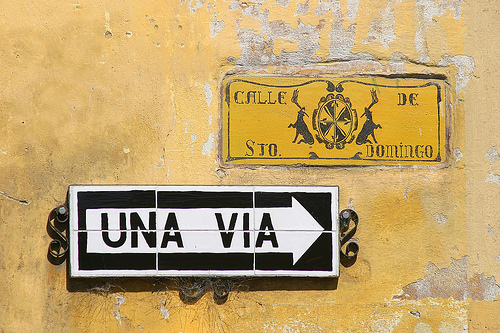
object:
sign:
[65, 184, 339, 279]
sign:
[223, 69, 451, 166]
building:
[0, 1, 500, 332]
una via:
[98, 210, 280, 249]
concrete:
[399, 255, 496, 308]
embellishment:
[338, 209, 359, 266]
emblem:
[286, 82, 386, 149]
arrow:
[85, 196, 328, 267]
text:
[232, 87, 290, 105]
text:
[243, 140, 282, 158]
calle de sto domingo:
[228, 87, 438, 162]